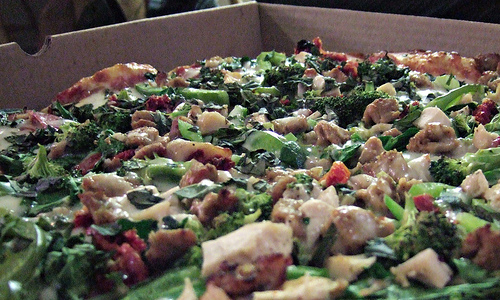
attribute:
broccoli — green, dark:
[61, 116, 104, 151]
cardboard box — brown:
[0, 0, 499, 111]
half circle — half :
[11, 35, 55, 59]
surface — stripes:
[164, 74, 379, 230]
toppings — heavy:
[0, 44, 497, 296]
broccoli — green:
[378, 196, 467, 257]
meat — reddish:
[102, 227, 145, 274]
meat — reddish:
[207, 241, 294, 283]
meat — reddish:
[28, 99, 68, 128]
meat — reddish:
[454, 211, 494, 261]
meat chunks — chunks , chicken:
[180, 134, 495, 290]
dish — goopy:
[6, 62, 494, 294]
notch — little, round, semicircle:
[11, 22, 90, 93]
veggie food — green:
[7, 24, 492, 298]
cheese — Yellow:
[371, 58, 445, 113]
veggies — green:
[97, 96, 369, 237]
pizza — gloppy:
[0, 36, 498, 297]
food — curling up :
[1, 28, 498, 284]